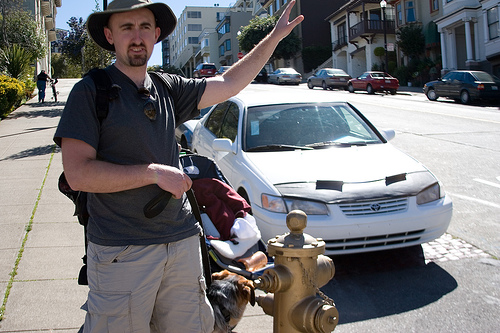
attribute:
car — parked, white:
[187, 82, 455, 272]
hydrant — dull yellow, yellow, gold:
[246, 204, 348, 332]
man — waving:
[49, 1, 310, 333]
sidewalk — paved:
[1, 76, 309, 332]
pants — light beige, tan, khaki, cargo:
[78, 235, 217, 332]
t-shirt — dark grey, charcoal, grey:
[52, 63, 211, 248]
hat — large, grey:
[84, 1, 178, 56]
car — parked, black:
[419, 67, 500, 109]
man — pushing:
[34, 67, 56, 108]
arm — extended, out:
[174, 0, 302, 120]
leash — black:
[140, 183, 178, 216]